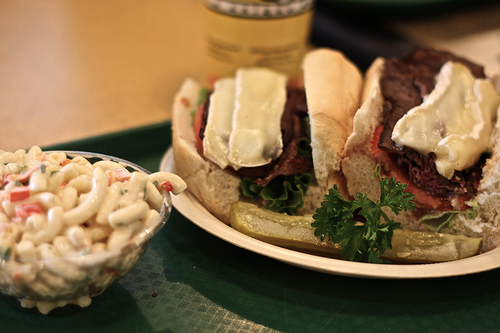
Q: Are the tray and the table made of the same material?
A: No, the tray is made of plastic and the table is made of wood.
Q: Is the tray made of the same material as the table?
A: No, the tray is made of plastic and the table is made of wood.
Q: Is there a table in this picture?
A: Yes, there is a table.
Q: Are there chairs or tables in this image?
A: Yes, there is a table.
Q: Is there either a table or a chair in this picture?
A: Yes, there is a table.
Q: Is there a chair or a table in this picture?
A: Yes, there is a table.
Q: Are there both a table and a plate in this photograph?
A: Yes, there are both a table and a plate.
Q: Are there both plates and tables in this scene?
A: Yes, there are both a table and a plate.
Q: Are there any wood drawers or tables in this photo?
A: Yes, there is a wood table.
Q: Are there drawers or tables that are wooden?
A: Yes, the table is wooden.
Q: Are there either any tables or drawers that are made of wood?
A: Yes, the table is made of wood.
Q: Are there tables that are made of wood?
A: Yes, there is a table that is made of wood.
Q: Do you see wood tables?
A: Yes, there is a table that is made of wood.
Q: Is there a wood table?
A: Yes, there is a table that is made of wood.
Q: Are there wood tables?
A: Yes, there is a table that is made of wood.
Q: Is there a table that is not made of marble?
A: Yes, there is a table that is made of wood.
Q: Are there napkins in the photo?
A: No, there are no napkins.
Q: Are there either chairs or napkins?
A: No, there are no napkins or chairs.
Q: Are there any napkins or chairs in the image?
A: No, there are no napkins or chairs.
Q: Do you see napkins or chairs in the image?
A: No, there are no napkins or chairs.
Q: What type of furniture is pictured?
A: The furniture is a table.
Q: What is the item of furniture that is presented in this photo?
A: The piece of furniture is a table.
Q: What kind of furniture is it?
A: The piece of furniture is a table.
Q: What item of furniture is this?
A: That is a table.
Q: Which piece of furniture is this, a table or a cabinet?
A: That is a table.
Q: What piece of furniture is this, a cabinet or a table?
A: That is a table.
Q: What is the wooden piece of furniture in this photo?
A: The piece of furniture is a table.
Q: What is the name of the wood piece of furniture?
A: The piece of furniture is a table.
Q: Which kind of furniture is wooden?
A: The furniture is a table.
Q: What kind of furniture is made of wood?
A: The furniture is a table.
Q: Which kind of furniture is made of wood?
A: The furniture is a table.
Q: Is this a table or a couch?
A: This is a table.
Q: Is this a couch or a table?
A: This is a table.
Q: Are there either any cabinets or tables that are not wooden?
A: No, there is a table but it is wooden.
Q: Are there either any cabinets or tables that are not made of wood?
A: No, there is a table but it is made of wood.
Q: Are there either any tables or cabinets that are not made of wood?
A: No, there is a table but it is made of wood.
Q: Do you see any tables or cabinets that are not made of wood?
A: No, there is a table but it is made of wood.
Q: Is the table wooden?
A: Yes, the table is wooden.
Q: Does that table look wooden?
A: Yes, the table is wooden.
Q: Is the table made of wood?
A: Yes, the table is made of wood.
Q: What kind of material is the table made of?
A: The table is made of wood.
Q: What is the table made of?
A: The table is made of wood.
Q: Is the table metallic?
A: No, the table is wooden.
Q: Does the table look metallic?
A: No, the table is wooden.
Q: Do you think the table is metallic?
A: No, the table is wooden.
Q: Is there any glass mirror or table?
A: No, there is a table but it is wooden.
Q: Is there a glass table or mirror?
A: No, there is a table but it is wooden.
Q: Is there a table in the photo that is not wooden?
A: No, there is a table but it is wooden.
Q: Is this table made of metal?
A: No, the table is made of wood.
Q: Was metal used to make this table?
A: No, the table is made of wood.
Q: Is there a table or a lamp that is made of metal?
A: No, there is a table but it is made of wood.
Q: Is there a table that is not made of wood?
A: No, there is a table but it is made of wood.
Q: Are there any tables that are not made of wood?
A: No, there is a table but it is made of wood.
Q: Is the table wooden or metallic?
A: The table is wooden.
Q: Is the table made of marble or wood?
A: The table is made of wood.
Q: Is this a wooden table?
A: Yes, this is a wooden table.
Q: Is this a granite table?
A: No, this is a wooden table.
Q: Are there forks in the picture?
A: No, there are no forks.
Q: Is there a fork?
A: No, there are no forks.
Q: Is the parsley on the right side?
A: Yes, the parsley is on the right of the image.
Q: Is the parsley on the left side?
A: No, the parsley is on the right of the image.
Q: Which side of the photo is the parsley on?
A: The parsley is on the right of the image.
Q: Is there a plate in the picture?
A: Yes, there is a plate.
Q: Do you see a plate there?
A: Yes, there is a plate.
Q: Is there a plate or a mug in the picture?
A: Yes, there is a plate.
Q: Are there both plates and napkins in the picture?
A: No, there is a plate but no napkins.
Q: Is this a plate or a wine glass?
A: This is a plate.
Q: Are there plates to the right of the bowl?
A: Yes, there is a plate to the right of the bowl.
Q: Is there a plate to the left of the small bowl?
A: No, the plate is to the right of the bowl.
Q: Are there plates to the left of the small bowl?
A: No, the plate is to the right of the bowl.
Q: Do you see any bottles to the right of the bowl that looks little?
A: No, there is a plate to the right of the bowl.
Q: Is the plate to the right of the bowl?
A: Yes, the plate is to the right of the bowl.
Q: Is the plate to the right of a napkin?
A: No, the plate is to the right of the bowl.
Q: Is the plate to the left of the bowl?
A: No, the plate is to the right of the bowl.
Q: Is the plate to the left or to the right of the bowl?
A: The plate is to the right of the bowl.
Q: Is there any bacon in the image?
A: No, there is no bacon.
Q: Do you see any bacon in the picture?
A: No, there is no bacon.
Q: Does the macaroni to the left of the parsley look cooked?
A: Yes, the macaroni is cooked.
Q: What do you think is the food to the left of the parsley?
A: The food is macaroni.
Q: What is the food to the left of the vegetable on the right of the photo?
A: The food is macaroni.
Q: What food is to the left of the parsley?
A: The food is macaroni.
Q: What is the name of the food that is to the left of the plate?
A: The food is macaroni.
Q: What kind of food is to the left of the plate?
A: The food is macaroni.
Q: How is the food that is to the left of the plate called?
A: The food is macaroni.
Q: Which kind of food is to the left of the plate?
A: The food is macaroni.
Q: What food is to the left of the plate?
A: The food is macaroni.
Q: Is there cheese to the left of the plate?
A: No, there is macaroni to the left of the plate.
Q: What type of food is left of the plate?
A: The food is macaroni.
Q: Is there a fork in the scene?
A: No, there are no forks.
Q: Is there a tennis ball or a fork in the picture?
A: No, there are no forks or tennis balls.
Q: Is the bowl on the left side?
A: Yes, the bowl is on the left of the image.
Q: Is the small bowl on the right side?
A: No, the bowl is on the left of the image.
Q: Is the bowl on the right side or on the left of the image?
A: The bowl is on the left of the image.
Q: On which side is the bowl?
A: The bowl is on the left of the image.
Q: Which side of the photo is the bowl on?
A: The bowl is on the left of the image.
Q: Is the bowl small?
A: Yes, the bowl is small.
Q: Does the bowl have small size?
A: Yes, the bowl is small.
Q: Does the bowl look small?
A: Yes, the bowl is small.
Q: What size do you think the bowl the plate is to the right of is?
A: The bowl is small.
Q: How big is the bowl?
A: The bowl is small.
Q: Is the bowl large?
A: No, the bowl is small.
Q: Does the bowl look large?
A: No, the bowl is small.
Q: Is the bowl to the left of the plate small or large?
A: The bowl is small.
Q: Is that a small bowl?
A: Yes, that is a small bowl.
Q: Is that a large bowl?
A: No, that is a small bowl.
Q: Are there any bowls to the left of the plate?
A: Yes, there is a bowl to the left of the plate.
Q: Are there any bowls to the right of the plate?
A: No, the bowl is to the left of the plate.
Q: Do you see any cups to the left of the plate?
A: No, there is a bowl to the left of the plate.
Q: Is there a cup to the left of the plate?
A: No, there is a bowl to the left of the plate.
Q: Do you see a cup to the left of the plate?
A: No, there is a bowl to the left of the plate.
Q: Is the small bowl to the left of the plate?
A: Yes, the bowl is to the left of the plate.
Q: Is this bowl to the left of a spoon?
A: No, the bowl is to the left of the plate.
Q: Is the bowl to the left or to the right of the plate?
A: The bowl is to the left of the plate.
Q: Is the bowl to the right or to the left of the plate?
A: The bowl is to the left of the plate.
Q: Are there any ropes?
A: No, there are no ropes.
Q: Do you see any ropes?
A: No, there are no ropes.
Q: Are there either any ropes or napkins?
A: No, there are no ropes or napkins.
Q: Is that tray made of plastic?
A: Yes, the tray is made of plastic.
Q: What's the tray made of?
A: The tray is made of plastic.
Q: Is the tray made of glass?
A: No, the tray is made of plastic.